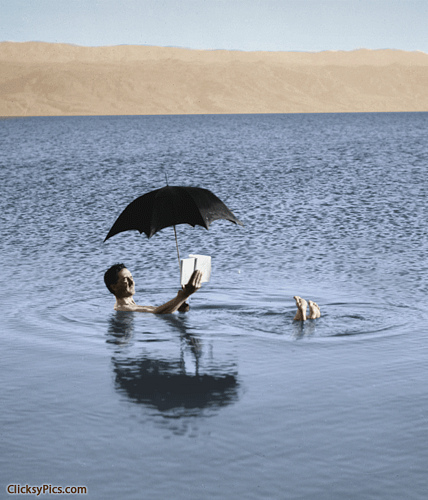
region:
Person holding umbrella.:
[124, 182, 256, 260]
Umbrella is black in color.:
[114, 208, 197, 260]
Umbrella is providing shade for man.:
[99, 198, 279, 331]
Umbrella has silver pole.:
[160, 210, 220, 301]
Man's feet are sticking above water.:
[286, 273, 353, 367]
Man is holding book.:
[173, 261, 220, 340]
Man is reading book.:
[167, 234, 259, 377]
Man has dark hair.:
[103, 256, 134, 311]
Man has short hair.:
[96, 256, 180, 357]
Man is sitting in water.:
[90, 253, 373, 342]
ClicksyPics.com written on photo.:
[3, 475, 94, 492]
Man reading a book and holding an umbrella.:
[48, 143, 370, 354]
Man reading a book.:
[88, 242, 325, 342]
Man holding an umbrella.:
[66, 149, 242, 340]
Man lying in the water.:
[62, 158, 364, 358]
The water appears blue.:
[9, 116, 416, 498]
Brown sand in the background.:
[10, 36, 420, 124]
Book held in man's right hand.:
[174, 247, 216, 308]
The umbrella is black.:
[107, 154, 225, 307]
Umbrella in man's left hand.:
[100, 168, 241, 312]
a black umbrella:
[105, 178, 243, 244]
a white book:
[175, 251, 212, 290]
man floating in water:
[102, 248, 327, 326]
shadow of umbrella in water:
[95, 330, 251, 427]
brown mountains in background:
[1, 37, 426, 114]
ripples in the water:
[19, 285, 419, 350]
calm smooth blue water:
[2, 355, 424, 498]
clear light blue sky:
[0, 0, 426, 53]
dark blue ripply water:
[2, 112, 426, 292]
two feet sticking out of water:
[287, 290, 324, 326]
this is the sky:
[123, 9, 263, 38]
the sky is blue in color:
[230, 16, 270, 35]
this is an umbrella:
[124, 192, 226, 229]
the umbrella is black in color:
[159, 200, 187, 218]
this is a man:
[105, 262, 154, 310]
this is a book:
[185, 251, 214, 293]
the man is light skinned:
[117, 298, 133, 304]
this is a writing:
[5, 483, 89, 494]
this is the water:
[211, 355, 378, 470]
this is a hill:
[121, 44, 256, 104]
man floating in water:
[92, 166, 329, 338]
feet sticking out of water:
[283, 289, 322, 331]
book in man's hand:
[172, 251, 220, 309]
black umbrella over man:
[103, 171, 247, 293]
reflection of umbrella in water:
[101, 347, 249, 428]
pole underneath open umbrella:
[166, 209, 198, 271]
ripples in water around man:
[34, 291, 402, 347]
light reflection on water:
[282, 371, 382, 432]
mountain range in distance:
[83, 39, 282, 120]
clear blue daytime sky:
[225, 1, 332, 37]